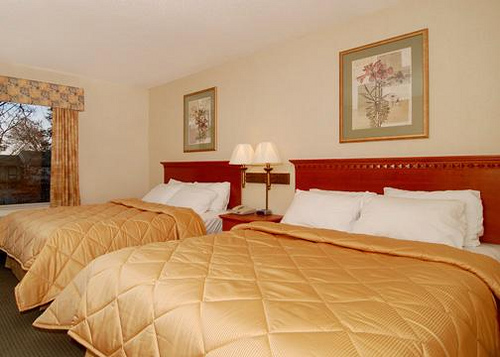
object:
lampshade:
[252, 141, 283, 164]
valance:
[0, 74, 85, 112]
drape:
[51, 106, 80, 208]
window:
[1, 102, 50, 204]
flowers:
[355, 60, 406, 129]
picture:
[338, 28, 429, 143]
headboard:
[287, 155, 499, 246]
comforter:
[29, 220, 498, 357]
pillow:
[353, 197, 466, 249]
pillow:
[281, 188, 363, 230]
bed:
[32, 219, 499, 355]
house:
[1, 155, 25, 185]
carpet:
[1, 302, 59, 356]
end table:
[218, 213, 283, 229]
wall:
[150, 1, 499, 193]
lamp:
[251, 143, 282, 189]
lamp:
[228, 143, 254, 188]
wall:
[71, 71, 148, 198]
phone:
[231, 205, 255, 215]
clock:
[256, 209, 272, 216]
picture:
[182, 85, 217, 153]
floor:
[0, 271, 66, 357]